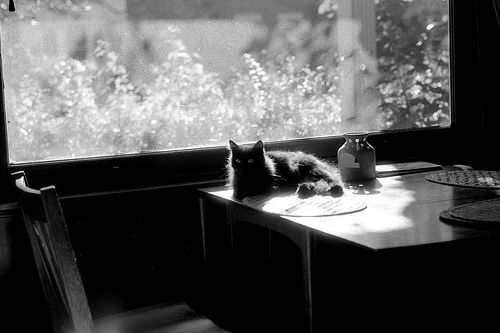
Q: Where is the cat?
A: On the table.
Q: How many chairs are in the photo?
A: One.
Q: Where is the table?
A: Next to the window.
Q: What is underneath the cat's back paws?
A: A placemat.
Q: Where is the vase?
A: Next to the cat.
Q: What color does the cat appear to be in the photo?
A: Black.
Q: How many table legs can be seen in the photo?
A: Two.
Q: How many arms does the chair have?
A: Zero.